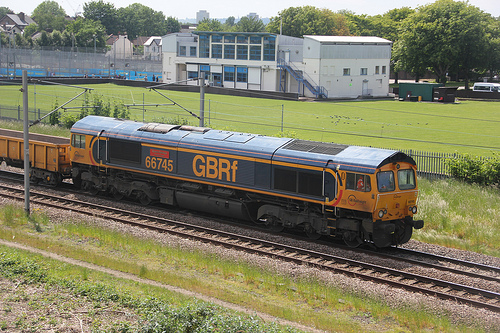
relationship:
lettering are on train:
[186, 148, 243, 184] [0, 115, 426, 252]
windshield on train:
[380, 163, 418, 196] [0, 115, 426, 252]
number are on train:
[137, 149, 179, 174] [0, 115, 426, 252]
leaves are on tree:
[392, 4, 493, 77] [380, 4, 498, 101]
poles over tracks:
[12, 72, 215, 221] [2, 160, 498, 309]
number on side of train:
[137, 149, 179, 174] [14, 109, 426, 257]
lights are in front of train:
[378, 199, 423, 217] [0, 115, 426, 252]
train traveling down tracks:
[14, 109, 426, 257] [2, 160, 498, 309]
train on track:
[14, 109, 426, 257] [0, 164, 498, 317]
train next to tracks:
[0, 115, 426, 252] [9, 161, 496, 324]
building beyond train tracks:
[158, 23, 403, 105] [3, 150, 497, 310]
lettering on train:
[184, 142, 244, 189] [0, 115, 426, 252]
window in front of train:
[381, 161, 418, 195] [0, 115, 426, 252]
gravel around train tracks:
[0, 153, 492, 328] [7, 165, 497, 306]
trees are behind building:
[0, 0, 494, 97] [149, 14, 396, 104]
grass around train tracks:
[2, 73, 497, 326] [3, 150, 497, 310]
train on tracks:
[0, 115, 426, 252] [108, 182, 480, 315]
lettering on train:
[186, 148, 243, 184] [41, 73, 423, 282]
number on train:
[137, 149, 179, 174] [31, 61, 430, 268]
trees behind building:
[403, 15, 470, 135] [117, 1, 401, 146]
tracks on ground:
[165, 190, 456, 308] [30, 155, 469, 325]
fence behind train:
[330, 122, 481, 187] [23, 82, 433, 277]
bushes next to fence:
[446, 120, 484, 189] [263, 102, 453, 172]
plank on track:
[125, 192, 182, 240] [35, 149, 464, 307]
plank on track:
[93, 190, 178, 292] [24, 167, 470, 310]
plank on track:
[188, 212, 224, 266] [30, 165, 449, 315]